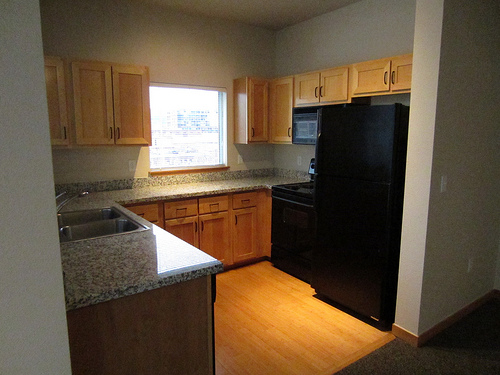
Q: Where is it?
A: This is at the kitchen.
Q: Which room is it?
A: It is a kitchen.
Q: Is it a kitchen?
A: Yes, it is a kitchen.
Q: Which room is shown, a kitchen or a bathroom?
A: It is a kitchen.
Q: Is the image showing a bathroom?
A: No, the picture is showing a kitchen.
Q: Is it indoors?
A: Yes, it is indoors.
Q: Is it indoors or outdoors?
A: It is indoors.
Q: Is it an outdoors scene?
A: No, it is indoors.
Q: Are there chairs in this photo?
A: No, there are no chairs.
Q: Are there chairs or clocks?
A: No, there are no chairs or clocks.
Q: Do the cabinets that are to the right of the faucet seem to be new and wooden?
A: Yes, the cabinets are new and wooden.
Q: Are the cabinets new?
A: Yes, the cabinets are new.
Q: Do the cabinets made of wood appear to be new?
A: Yes, the cabinets are new.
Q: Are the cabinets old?
A: No, the cabinets are new.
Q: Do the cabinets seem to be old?
A: No, the cabinets are new.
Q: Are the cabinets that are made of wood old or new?
A: The cabinets are new.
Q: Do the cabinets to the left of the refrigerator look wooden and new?
A: Yes, the cabinets are wooden and new.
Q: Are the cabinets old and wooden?
A: No, the cabinets are wooden but new.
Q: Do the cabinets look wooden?
A: Yes, the cabinets are wooden.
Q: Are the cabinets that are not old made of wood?
A: Yes, the cabinets are made of wood.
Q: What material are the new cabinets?
A: The cabinets are made of wood.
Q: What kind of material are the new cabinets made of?
A: The cabinets are made of wood.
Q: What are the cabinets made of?
A: The cabinets are made of wood.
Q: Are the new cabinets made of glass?
A: No, the cabinets are made of wood.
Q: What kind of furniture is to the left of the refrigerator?
A: The pieces of furniture are cabinets.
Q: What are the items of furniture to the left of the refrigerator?
A: The pieces of furniture are cabinets.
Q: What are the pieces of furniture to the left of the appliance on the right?
A: The pieces of furniture are cabinets.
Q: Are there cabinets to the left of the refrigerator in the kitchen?
A: Yes, there are cabinets to the left of the freezer.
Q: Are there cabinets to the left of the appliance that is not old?
A: Yes, there are cabinets to the left of the freezer.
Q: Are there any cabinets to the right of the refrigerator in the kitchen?
A: No, the cabinets are to the left of the freezer.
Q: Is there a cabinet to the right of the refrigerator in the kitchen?
A: No, the cabinets are to the left of the freezer.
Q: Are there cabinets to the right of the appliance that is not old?
A: No, the cabinets are to the left of the freezer.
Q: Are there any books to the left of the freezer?
A: No, there are cabinets to the left of the freezer.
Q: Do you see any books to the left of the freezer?
A: No, there are cabinets to the left of the freezer.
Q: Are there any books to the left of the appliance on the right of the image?
A: No, there are cabinets to the left of the freezer.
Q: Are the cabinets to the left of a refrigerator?
A: Yes, the cabinets are to the left of a refrigerator.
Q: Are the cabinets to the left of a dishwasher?
A: No, the cabinets are to the left of a refrigerator.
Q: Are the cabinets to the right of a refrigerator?
A: No, the cabinets are to the left of a refrigerator.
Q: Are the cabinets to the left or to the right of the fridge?
A: The cabinets are to the left of the fridge.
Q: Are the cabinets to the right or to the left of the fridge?
A: The cabinets are to the left of the fridge.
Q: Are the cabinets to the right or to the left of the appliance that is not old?
A: The cabinets are to the left of the fridge.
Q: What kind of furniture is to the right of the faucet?
A: The pieces of furniture are cabinets.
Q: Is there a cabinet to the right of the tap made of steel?
A: Yes, there are cabinets to the right of the tap.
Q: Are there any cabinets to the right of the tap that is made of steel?
A: Yes, there are cabinets to the right of the tap.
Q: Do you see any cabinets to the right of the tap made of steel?
A: Yes, there are cabinets to the right of the tap.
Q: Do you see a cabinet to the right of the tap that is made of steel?
A: Yes, there are cabinets to the right of the tap.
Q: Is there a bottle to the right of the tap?
A: No, there are cabinets to the right of the tap.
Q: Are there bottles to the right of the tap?
A: No, there are cabinets to the right of the tap.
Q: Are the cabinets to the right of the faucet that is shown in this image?
A: Yes, the cabinets are to the right of the faucet.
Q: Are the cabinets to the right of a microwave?
A: No, the cabinets are to the right of the faucet.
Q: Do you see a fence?
A: No, there are no fences.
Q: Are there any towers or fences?
A: No, there are no fences or towers.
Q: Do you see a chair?
A: No, there are no chairs.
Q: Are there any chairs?
A: No, there are no chairs.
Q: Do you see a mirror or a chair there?
A: No, there are no chairs or mirrors.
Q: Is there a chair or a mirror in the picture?
A: No, there are no chairs or mirrors.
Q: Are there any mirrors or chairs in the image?
A: No, there are no chairs or mirrors.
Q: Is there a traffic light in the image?
A: No, there are no traffic lights.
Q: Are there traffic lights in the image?
A: No, there are no traffic lights.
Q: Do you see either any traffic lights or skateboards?
A: No, there are no traffic lights or skateboards.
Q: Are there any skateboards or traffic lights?
A: No, there are no traffic lights or skateboards.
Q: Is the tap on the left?
A: Yes, the tap is on the left of the image.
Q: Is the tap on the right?
A: No, the tap is on the left of the image.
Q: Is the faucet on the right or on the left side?
A: The faucet is on the left of the image.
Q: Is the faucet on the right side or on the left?
A: The faucet is on the left of the image.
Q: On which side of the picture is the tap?
A: The tap is on the left of the image.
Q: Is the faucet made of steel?
A: Yes, the faucet is made of steel.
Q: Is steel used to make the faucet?
A: Yes, the faucet is made of steel.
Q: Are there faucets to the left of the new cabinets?
A: Yes, there is a faucet to the left of the cabinets.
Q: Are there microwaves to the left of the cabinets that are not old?
A: No, there is a faucet to the left of the cabinets.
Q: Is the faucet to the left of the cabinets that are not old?
A: Yes, the faucet is to the left of the cabinets.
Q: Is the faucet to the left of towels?
A: No, the faucet is to the left of the cabinets.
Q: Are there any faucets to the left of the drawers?
A: Yes, there is a faucet to the left of the drawers.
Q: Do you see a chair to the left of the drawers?
A: No, there is a faucet to the left of the drawers.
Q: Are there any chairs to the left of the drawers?
A: No, there is a faucet to the left of the drawers.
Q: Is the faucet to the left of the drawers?
A: Yes, the faucet is to the left of the drawers.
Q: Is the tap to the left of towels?
A: No, the tap is to the left of the drawers.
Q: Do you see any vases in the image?
A: No, there are no vases.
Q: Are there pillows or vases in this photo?
A: No, there are no vases or pillows.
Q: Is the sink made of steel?
A: Yes, the sink is made of steel.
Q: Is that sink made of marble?
A: No, the sink is made of steel.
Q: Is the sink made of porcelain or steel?
A: The sink is made of steel.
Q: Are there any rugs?
A: No, there are no rugs.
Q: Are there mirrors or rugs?
A: No, there are no rugs or mirrors.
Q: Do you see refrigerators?
A: Yes, there is a refrigerator.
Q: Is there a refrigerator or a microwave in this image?
A: Yes, there is a refrigerator.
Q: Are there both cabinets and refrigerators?
A: Yes, there are both a refrigerator and cabinets.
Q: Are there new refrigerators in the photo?
A: Yes, there is a new refrigerator.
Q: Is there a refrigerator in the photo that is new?
A: Yes, there is a refrigerator that is new.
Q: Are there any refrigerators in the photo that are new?
A: Yes, there is a refrigerator that is new.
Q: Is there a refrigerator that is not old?
A: Yes, there is an new refrigerator.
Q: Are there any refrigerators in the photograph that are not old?
A: Yes, there is an new refrigerator.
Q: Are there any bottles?
A: No, there are no bottles.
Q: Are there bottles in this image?
A: No, there are no bottles.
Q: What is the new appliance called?
A: The appliance is a refrigerator.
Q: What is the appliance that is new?
A: The appliance is a refrigerator.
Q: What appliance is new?
A: The appliance is a refrigerator.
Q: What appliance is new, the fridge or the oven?
A: The fridge is new.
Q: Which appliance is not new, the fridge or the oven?
A: The oven is not new.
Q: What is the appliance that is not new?
A: The appliance is an oven.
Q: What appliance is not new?
A: The appliance is an oven.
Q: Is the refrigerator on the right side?
A: Yes, the refrigerator is on the right of the image.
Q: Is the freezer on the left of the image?
A: No, the freezer is on the right of the image.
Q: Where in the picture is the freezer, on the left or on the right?
A: The freezer is on the right of the image.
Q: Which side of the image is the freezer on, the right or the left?
A: The freezer is on the right of the image.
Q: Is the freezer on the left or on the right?
A: The freezer is on the right of the image.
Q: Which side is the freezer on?
A: The freezer is on the right of the image.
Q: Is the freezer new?
A: Yes, the freezer is new.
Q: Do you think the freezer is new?
A: Yes, the freezer is new.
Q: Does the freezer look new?
A: Yes, the freezer is new.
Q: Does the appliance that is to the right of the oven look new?
A: Yes, the freezer is new.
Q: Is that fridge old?
A: No, the fridge is new.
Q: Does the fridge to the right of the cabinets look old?
A: No, the freezer is new.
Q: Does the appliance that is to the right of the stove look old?
A: No, the freezer is new.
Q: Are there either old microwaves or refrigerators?
A: No, there is a refrigerator but it is new.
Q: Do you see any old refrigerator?
A: No, there is a refrigerator but it is new.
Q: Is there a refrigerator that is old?
A: No, there is a refrigerator but it is new.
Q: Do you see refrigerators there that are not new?
A: No, there is a refrigerator but it is new.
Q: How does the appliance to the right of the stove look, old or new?
A: The fridge is new.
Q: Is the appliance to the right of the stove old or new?
A: The fridge is new.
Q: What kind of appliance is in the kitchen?
A: The appliance is a refrigerator.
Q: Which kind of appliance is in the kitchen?
A: The appliance is a refrigerator.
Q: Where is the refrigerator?
A: The refrigerator is in the kitchen.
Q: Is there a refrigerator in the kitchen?
A: Yes, there is a refrigerator in the kitchen.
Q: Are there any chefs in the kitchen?
A: No, there is a refrigerator in the kitchen.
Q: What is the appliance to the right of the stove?
A: The appliance is a refrigerator.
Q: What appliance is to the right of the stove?
A: The appliance is a refrigerator.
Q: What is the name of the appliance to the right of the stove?
A: The appliance is a refrigerator.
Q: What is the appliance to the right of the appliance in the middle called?
A: The appliance is a refrigerator.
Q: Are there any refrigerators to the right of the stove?
A: Yes, there is a refrigerator to the right of the stove.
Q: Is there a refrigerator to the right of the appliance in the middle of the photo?
A: Yes, there is a refrigerator to the right of the stove.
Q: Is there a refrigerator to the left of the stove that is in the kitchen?
A: No, the refrigerator is to the right of the stove.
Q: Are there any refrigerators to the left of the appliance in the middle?
A: No, the refrigerator is to the right of the stove.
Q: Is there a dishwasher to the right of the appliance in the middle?
A: No, there is a refrigerator to the right of the stove.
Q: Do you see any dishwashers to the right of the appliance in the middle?
A: No, there is a refrigerator to the right of the stove.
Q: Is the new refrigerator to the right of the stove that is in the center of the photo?
A: Yes, the refrigerator is to the right of the stove.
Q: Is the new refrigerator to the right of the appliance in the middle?
A: Yes, the refrigerator is to the right of the stove.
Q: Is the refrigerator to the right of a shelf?
A: No, the refrigerator is to the right of the stove.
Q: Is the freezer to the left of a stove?
A: No, the freezer is to the right of a stove.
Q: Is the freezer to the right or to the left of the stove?
A: The freezer is to the right of the stove.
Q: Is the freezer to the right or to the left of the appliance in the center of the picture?
A: The freezer is to the right of the stove.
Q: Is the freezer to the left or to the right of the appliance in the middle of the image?
A: The freezer is to the right of the stove.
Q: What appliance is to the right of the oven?
A: The appliance is a refrigerator.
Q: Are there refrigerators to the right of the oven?
A: Yes, there is a refrigerator to the right of the oven.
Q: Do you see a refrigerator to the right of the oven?
A: Yes, there is a refrigerator to the right of the oven.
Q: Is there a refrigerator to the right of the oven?
A: Yes, there is a refrigerator to the right of the oven.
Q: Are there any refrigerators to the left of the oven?
A: No, the refrigerator is to the right of the oven.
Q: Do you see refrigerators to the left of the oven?
A: No, the refrigerator is to the right of the oven.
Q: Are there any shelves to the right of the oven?
A: No, there is a refrigerator to the right of the oven.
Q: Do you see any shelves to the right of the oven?
A: No, there is a refrigerator to the right of the oven.